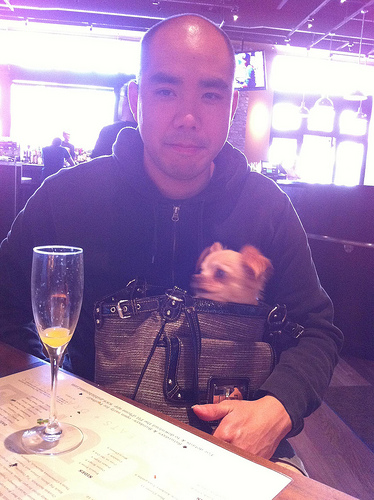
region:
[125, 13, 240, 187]
Younger man starring into camera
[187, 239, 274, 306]
Cute small dog inside purse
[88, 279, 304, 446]
Purse with a dog inside of it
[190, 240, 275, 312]
Puppy's head sticking out of purse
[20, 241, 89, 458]
Wine glass with little cocktail left inside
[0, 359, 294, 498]
Menu items on table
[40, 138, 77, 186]
Person waiting at the bar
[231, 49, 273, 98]
Television on in the bar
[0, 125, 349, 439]
Black jacket with zipper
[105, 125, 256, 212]
Black hoodie pulled down on young man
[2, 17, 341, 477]
Person holding a small puppy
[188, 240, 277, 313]
Puppy in a handbag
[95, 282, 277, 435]
Handbag used to hold the puppy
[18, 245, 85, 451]
Glass on whine on the table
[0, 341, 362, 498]
Wooden table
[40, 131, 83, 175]
Couple of people behind the person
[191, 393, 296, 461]
Left land of the person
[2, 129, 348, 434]
Sweater of the person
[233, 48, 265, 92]
Flat screen television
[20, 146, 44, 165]
Several bottles of alcohol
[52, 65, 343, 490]
man holding purse with dog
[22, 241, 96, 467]
mimosa glass nearly empty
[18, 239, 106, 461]
mimosa glass sitting on menu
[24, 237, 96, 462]
mimosa in champagne flute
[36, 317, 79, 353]
drink is orange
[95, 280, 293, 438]
purse is gray and black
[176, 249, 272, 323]
dog sitting in purse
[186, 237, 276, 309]
dog has brown ears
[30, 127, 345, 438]
man wearing black hoodie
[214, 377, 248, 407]
silver closure on purse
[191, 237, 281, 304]
puppy in a bag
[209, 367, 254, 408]
phone in man's hand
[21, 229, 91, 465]
champagne glass on table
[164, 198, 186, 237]
zipper on a jacket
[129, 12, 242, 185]
face of a man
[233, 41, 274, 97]
television on the ceiling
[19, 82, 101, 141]
light shining through the window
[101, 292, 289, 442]
bag in man's arms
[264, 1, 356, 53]
ceiling of a restaurant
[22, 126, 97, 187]
people at a bar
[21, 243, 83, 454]
champagne glass with orange juice in it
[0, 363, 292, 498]
white laminated paper menu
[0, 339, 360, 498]
medium brown wood table top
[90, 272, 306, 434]
leather and cloth designer bag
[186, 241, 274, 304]
small tan fluffy dog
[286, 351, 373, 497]
wood and carpet tiled floor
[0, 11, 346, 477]
Asian man with a shaved head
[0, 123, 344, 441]
black sweat jacket with a hood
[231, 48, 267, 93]
television that is on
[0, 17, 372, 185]
wall of windows